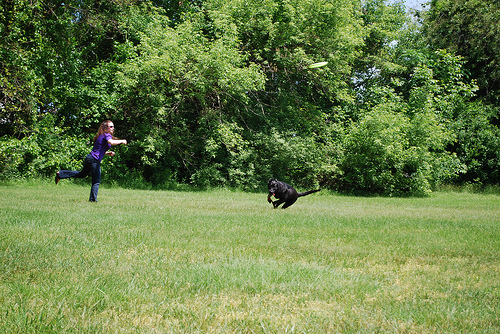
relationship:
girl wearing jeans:
[52, 112, 130, 207] [53, 153, 104, 205]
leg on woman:
[89, 162, 101, 204] [52, 112, 130, 207]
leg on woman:
[46, 158, 94, 185] [52, 112, 130, 207]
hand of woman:
[120, 136, 131, 147] [52, 112, 130, 207]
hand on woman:
[108, 147, 118, 158] [52, 112, 130, 207]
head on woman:
[101, 119, 119, 134] [52, 112, 130, 207]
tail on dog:
[297, 187, 324, 198] [267, 176, 323, 215]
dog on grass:
[267, 176, 323, 215] [126, 210, 214, 256]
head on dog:
[262, 176, 280, 196] [267, 176, 323, 215]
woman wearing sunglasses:
[52, 112, 130, 207] [108, 124, 116, 130]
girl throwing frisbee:
[52, 112, 130, 207] [306, 57, 334, 69]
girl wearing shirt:
[52, 112, 130, 207] [90, 134, 111, 163]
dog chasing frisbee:
[267, 176, 323, 215] [306, 57, 334, 69]